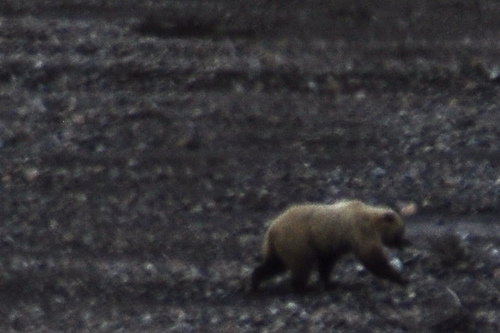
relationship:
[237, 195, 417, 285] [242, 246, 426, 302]
bear has legs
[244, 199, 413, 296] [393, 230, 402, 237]
bear has eye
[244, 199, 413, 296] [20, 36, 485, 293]
bear walking in field